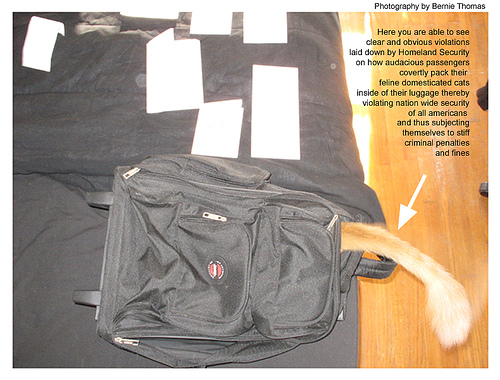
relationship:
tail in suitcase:
[340, 222, 472, 348] [72, 155, 341, 369]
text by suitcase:
[347, 28, 470, 158] [72, 155, 341, 369]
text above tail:
[347, 28, 470, 158] [340, 222, 472, 348]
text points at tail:
[347, 28, 470, 158] [340, 222, 472, 348]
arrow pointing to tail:
[397, 172, 427, 230] [340, 222, 472, 348]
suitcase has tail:
[72, 155, 341, 369] [340, 222, 472, 348]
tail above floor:
[340, 222, 472, 348] [336, 11, 489, 368]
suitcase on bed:
[72, 155, 341, 369] [13, 12, 360, 370]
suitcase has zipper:
[72, 155, 341, 369] [123, 167, 140, 179]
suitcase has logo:
[72, 155, 341, 369] [206, 255, 227, 282]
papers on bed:
[145, 28, 245, 161] [13, 12, 360, 370]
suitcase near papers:
[72, 155, 341, 369] [145, 28, 245, 161]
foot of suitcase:
[72, 289, 104, 309] [72, 155, 341, 369]